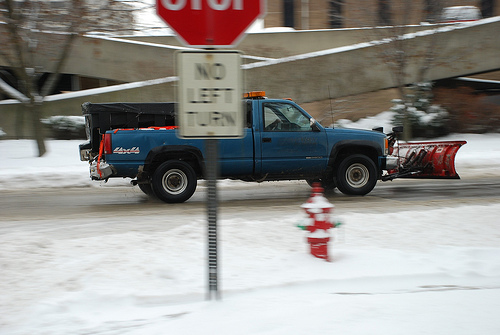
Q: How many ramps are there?
A: 2.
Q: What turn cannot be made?
A: Left turn.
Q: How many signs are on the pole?
A: Two.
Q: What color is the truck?
A: Blue.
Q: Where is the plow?
A: On the front of the truck.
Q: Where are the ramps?
A: Behind the truck.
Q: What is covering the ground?
A: Snow.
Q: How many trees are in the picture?
A: Two.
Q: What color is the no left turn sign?
A: Black and white.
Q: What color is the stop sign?
A: Red and white.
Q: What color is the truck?
A: Blue.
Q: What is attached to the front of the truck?
A: Snow plow.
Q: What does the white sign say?
A: No Left Turn.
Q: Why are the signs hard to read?
A: They are blurry.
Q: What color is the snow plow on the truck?
A: Red.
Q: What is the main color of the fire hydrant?
A: Red.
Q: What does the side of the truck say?
A: 4x4.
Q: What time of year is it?
A: Winter.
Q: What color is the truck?
A: Blue.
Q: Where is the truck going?
A: To the right.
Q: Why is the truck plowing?
A: Clearing the snow.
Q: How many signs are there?
A: 2.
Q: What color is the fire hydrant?
A: Red.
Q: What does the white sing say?
A: No left turn.